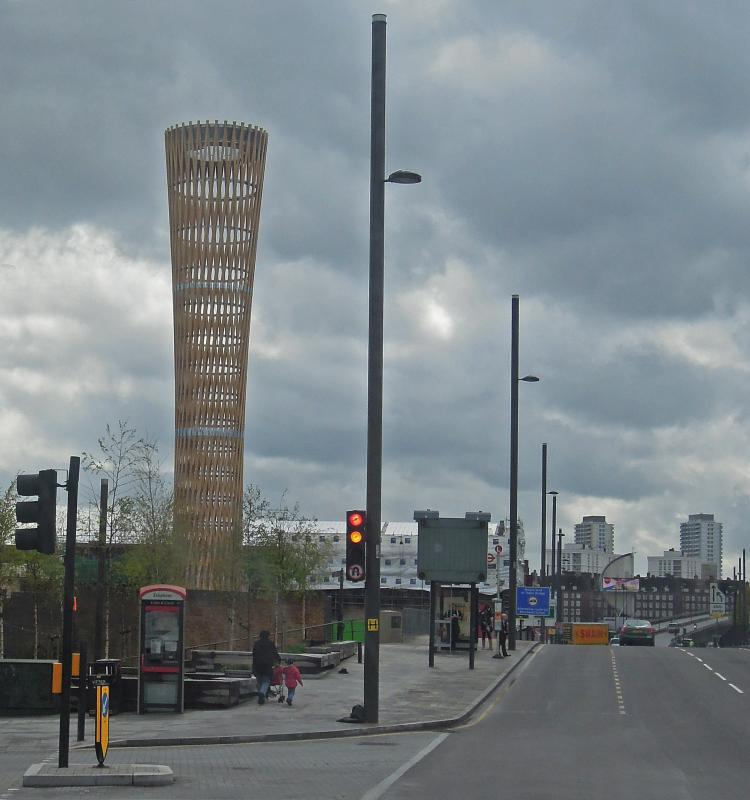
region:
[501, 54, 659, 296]
grey and white sky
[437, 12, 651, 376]
clouds are dark grey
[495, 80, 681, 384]
puffy clouds in sky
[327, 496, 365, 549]
red and yellow lights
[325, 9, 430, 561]
lights on tall pole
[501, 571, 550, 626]
blue and white sign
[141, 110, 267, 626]
tall and brown structure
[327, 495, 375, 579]
red and yellow lights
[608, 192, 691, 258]
white clouds in blue sky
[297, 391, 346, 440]
white clouds in blue sky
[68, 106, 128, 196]
white clouds in blue sky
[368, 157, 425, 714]
a street light on a pole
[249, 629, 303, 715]
a person walking with a child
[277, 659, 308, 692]
a girl wearing a pink coat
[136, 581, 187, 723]
a red, black, and white telephone booth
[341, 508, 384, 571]
a traffic signal attached to a pole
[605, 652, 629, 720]
white painted lines on a road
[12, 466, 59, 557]
a black traffic signal housing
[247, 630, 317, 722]
people on a sidewalk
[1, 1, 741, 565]
an overcast sky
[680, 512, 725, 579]
a white multi story building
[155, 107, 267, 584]
a tall brown piece of artwork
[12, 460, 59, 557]
a black traffic light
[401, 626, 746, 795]
a large paved road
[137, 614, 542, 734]
a long sidewalk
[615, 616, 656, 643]
car driving down the road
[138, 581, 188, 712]
phone booth on the side of the road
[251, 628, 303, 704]
woman and small child walking down the road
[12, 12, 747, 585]
mostly cloudy and overcast sky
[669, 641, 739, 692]
white dashed lines painted down the road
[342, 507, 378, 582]
traffic light attached to the side of a pole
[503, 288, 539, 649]
tall black light post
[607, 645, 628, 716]
yellow dotted line on the road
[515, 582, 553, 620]
blue informational sign on the road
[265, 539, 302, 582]
green leaves on the tree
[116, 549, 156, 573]
green leaves on the tree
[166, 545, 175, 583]
green leaves on the tree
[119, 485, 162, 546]
green leaves on the tree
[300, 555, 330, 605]
green leaves on the tree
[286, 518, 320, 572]
green leaves on the tree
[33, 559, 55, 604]
green leaves on the tree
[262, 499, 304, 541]
green leaves on the tree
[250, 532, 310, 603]
green leaves on the tree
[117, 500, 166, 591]
green leaves on the tree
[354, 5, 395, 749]
light pole with fixture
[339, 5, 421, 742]
light pole with traffic signal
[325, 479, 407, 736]
traffic signal on pole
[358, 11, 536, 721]
two light poles with fixtures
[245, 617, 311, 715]
woman and child walking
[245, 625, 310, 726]
woman pushing stroller with child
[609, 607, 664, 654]
car driving down the street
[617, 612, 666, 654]
car driving on the roadway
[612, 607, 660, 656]
car driving over the top of the hill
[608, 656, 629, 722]
painted lane markings on street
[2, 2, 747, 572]
cloud cover in daytime sky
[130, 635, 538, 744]
curb on edge of sidewalk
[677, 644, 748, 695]
white broken lines on sidewalk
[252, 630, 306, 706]
adult and child walking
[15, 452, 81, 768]
side of traffic light on pole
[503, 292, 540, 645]
street light on vertical pole